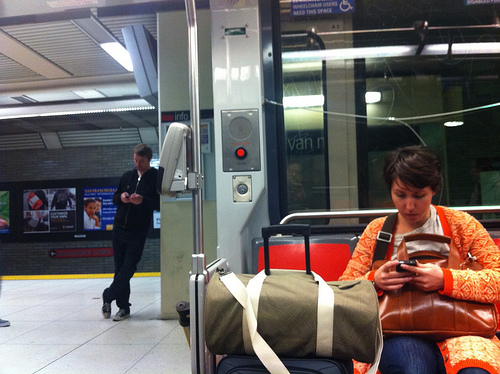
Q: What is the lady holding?
A: Cell phone.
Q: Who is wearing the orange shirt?
A: Lady.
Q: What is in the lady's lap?
A: Brown leather purse.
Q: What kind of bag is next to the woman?
A: Olive duffle bag with white straps.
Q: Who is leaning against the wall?
A: The guy.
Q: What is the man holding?
A: Cell phone.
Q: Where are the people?
A: Subway stop.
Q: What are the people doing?
A: Waiting for their train.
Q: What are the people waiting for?
A: Train.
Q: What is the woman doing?
A: Using a cell phone.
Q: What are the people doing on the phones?
A: Texting.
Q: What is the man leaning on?
A: A wall.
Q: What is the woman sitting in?
A: A chair.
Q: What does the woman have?
A: Bags.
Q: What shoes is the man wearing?
A: Black sneakers.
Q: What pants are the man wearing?
A: Black.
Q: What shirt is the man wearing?
A: Sweatshirt.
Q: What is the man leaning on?
A: A wall.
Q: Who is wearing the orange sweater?
A: Woman on the bench.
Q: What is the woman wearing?
A: White shirt and orange coat.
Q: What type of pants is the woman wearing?
A: Blue jeans.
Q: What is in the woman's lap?
A: Leather purse.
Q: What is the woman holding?
A: Cell phone.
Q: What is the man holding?
A: Cell phone.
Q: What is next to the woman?
A: Canvas bag with white stripes.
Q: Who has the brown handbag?
A: The woman.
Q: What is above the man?
A: Metal ceiling.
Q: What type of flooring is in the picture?
A: Tile.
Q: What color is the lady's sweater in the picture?
A: The lady's sweater is orange.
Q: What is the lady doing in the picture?
A: The lady is looking at her iphone in the picture.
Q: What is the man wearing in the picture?
A: The man is wearing a sweater, pants and sneakers.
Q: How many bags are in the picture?
A: Two bags in the picture.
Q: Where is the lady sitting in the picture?
A: The lady is sitting on a bench in the picture.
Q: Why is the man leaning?
A: The man is leaning so he can check his iphone.